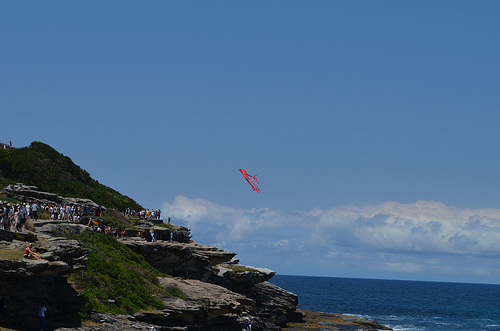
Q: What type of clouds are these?
A: Low lying.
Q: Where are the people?
A: Top of cliffs.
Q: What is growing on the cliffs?
A: Grass.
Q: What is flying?
A: Kite.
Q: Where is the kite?
A: Sky.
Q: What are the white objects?
A: Clouds.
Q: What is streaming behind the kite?
A: Tails.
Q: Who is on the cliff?
A: Group of people.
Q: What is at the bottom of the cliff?
A: Water.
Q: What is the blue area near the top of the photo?
A: The sky.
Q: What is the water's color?
A: Blue.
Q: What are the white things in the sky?
A: Clouds.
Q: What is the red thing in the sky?
A: A kite.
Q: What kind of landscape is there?
A: Rocky.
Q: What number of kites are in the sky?
A: One.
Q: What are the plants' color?
A: Green.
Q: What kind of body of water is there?
A: An ocean.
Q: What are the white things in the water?
A: Waves.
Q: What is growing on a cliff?
A: Grass.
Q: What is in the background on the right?
A: The ocean.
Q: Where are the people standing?
A: On the rocks.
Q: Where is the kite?
A: In the air.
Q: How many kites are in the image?
A: One.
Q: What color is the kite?
A: Red.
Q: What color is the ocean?
A: Blue.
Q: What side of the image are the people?
A: Left.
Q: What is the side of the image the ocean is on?
A: Right.